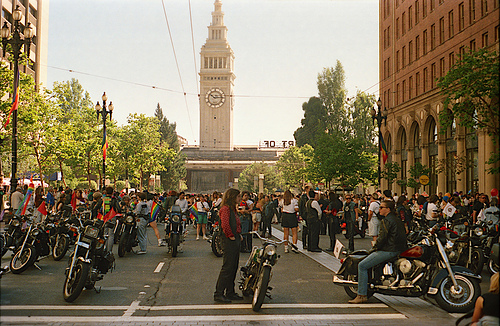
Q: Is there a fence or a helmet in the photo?
A: No, there are no fences or helmets.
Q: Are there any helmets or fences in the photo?
A: No, there are no fences or helmets.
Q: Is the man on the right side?
A: Yes, the man is on the right of the image.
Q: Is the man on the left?
A: No, the man is on the right of the image.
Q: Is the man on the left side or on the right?
A: The man is on the right of the image.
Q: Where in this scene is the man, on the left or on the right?
A: The man is on the right of the image.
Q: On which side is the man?
A: The man is on the right of the image.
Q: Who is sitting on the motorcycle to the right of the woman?
A: The man is sitting on the motorbike.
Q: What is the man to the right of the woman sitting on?
A: The man is sitting on the motorcycle.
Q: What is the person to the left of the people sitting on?
A: The man is sitting on the motorcycle.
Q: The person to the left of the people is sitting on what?
A: The man is sitting on the motorcycle.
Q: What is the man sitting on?
A: The man is sitting on the motorcycle.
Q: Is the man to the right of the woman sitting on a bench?
A: No, the man is sitting on the motorcycle.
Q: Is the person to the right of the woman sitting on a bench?
A: No, the man is sitting on the motorcycle.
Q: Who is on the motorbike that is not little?
A: The man is on the motorbike.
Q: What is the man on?
A: The man is on the motorcycle.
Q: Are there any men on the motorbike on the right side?
A: Yes, there is a man on the motorcycle.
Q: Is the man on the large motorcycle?
A: Yes, the man is on the motorbike.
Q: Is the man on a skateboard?
A: No, the man is on the motorbike.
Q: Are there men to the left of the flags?
A: Yes, there is a man to the left of the flags.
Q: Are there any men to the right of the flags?
A: No, the man is to the left of the flags.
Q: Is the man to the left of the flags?
A: Yes, the man is to the left of the flags.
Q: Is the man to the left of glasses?
A: No, the man is to the left of the flags.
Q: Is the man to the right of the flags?
A: No, the man is to the left of the flags.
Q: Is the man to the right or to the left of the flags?
A: The man is to the left of the flags.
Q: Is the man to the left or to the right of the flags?
A: The man is to the left of the flags.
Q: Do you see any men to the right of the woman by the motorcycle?
A: Yes, there is a man to the right of the woman.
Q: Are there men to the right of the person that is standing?
A: Yes, there is a man to the right of the woman.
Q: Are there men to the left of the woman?
A: No, the man is to the right of the woman.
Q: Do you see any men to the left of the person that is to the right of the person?
A: No, the man is to the right of the woman.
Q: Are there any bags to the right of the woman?
A: No, there is a man to the right of the woman.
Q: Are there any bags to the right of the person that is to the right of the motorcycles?
A: No, there is a man to the right of the woman.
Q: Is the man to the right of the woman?
A: Yes, the man is to the right of the woman.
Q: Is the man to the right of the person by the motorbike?
A: Yes, the man is to the right of the woman.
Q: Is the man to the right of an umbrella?
A: No, the man is to the right of the woman.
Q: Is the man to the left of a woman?
A: No, the man is to the right of a woman.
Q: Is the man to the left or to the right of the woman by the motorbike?
A: The man is to the right of the woman.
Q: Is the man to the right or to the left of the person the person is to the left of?
A: The man is to the right of the woman.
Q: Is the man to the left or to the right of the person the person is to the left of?
A: The man is to the right of the woman.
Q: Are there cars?
A: No, there are no cars.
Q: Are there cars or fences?
A: No, there are no cars or fences.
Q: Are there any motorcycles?
A: Yes, there is a motorcycle.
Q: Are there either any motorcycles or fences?
A: Yes, there is a motorcycle.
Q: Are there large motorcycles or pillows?
A: Yes, there is a large motorcycle.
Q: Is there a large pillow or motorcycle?
A: Yes, there is a large motorcycle.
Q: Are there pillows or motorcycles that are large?
A: Yes, the motorcycle is large.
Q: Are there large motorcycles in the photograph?
A: Yes, there is a large motorcycle.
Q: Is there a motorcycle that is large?
A: Yes, there is a motorcycle that is large.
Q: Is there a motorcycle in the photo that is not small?
A: Yes, there is a large motorcycle.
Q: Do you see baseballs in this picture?
A: No, there are no baseballs.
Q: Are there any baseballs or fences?
A: No, there are no baseballs or fences.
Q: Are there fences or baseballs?
A: No, there are no baseballs or fences.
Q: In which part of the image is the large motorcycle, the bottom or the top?
A: The motorbike is in the bottom of the image.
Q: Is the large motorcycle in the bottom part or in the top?
A: The motorbike is in the bottom of the image.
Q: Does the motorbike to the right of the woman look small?
A: No, the motorcycle is large.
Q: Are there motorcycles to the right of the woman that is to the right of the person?
A: Yes, there is a motorcycle to the right of the woman.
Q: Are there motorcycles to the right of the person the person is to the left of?
A: Yes, there is a motorcycle to the right of the woman.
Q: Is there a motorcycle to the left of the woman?
A: No, the motorcycle is to the right of the woman.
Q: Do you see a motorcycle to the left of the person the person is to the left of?
A: No, the motorcycle is to the right of the woman.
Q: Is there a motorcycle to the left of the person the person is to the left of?
A: No, the motorcycle is to the right of the woman.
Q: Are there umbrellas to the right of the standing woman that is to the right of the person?
A: No, there is a motorcycle to the right of the woman.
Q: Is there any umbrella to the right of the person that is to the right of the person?
A: No, there is a motorcycle to the right of the woman.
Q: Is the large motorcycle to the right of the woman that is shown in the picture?
A: Yes, the motorbike is to the right of the woman.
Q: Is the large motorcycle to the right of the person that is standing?
A: Yes, the motorbike is to the right of the woman.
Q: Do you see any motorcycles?
A: Yes, there are motorcycles.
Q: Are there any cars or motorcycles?
A: Yes, there are motorcycles.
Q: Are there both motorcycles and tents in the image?
A: No, there are motorcycles but no tents.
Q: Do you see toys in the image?
A: No, there are no toys.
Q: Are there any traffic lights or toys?
A: No, there are no toys or traffic lights.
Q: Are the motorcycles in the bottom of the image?
A: Yes, the motorcycles are in the bottom of the image.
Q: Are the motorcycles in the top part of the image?
A: No, the motorcycles are in the bottom of the image.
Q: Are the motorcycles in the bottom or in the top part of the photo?
A: The motorcycles are in the bottom of the image.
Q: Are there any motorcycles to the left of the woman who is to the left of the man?
A: Yes, there are motorcycles to the left of the woman.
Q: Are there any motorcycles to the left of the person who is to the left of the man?
A: Yes, there are motorcycles to the left of the woman.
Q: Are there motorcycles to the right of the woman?
A: No, the motorcycles are to the left of the woman.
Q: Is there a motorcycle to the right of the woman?
A: No, the motorcycles are to the left of the woman.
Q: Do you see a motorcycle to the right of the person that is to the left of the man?
A: No, the motorcycles are to the left of the woman.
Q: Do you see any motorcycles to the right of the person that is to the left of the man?
A: No, the motorcycles are to the left of the woman.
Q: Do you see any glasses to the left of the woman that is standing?
A: No, there are motorcycles to the left of the woman.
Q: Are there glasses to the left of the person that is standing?
A: No, there are motorcycles to the left of the woman.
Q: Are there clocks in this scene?
A: Yes, there is a clock.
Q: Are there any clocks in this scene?
A: Yes, there is a clock.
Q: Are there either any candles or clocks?
A: Yes, there is a clock.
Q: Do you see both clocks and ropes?
A: No, there is a clock but no ropes.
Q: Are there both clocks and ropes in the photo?
A: No, there is a clock but no ropes.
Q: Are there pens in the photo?
A: No, there are no pens.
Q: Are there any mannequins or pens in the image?
A: No, there are no pens or mannequins.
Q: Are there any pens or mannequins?
A: No, there are no pens or mannequins.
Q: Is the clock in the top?
A: Yes, the clock is in the top of the image.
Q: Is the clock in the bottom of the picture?
A: No, the clock is in the top of the image.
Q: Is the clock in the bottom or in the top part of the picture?
A: The clock is in the top of the image.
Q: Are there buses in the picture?
A: No, there are no buses.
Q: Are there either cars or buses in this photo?
A: No, there are no buses or cars.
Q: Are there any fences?
A: No, there are no fences.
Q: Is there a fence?
A: No, there are no fences.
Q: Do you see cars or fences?
A: No, there are no fences or cars.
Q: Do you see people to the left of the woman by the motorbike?
A: Yes, there is a person to the left of the woman.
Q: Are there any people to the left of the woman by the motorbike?
A: Yes, there is a person to the left of the woman.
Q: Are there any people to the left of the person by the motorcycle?
A: Yes, there is a person to the left of the woman.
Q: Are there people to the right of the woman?
A: No, the person is to the left of the woman.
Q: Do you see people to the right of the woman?
A: No, the person is to the left of the woman.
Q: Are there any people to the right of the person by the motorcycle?
A: No, the person is to the left of the woman.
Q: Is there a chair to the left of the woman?
A: No, there is a person to the left of the woman.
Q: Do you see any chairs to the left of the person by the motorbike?
A: No, there is a person to the left of the woman.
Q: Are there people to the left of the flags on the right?
A: Yes, there are people to the left of the flags.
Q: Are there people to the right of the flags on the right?
A: No, the people are to the left of the flags.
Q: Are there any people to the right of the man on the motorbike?
A: Yes, there are people to the right of the man.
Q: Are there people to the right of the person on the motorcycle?
A: Yes, there are people to the right of the man.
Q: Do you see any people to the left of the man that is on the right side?
A: No, the people are to the right of the man.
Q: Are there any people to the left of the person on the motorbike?
A: No, the people are to the right of the man.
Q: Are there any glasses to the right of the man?
A: No, there are people to the right of the man.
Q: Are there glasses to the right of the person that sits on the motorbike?
A: No, there are people to the right of the man.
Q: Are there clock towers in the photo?
A: Yes, there is a clock tower.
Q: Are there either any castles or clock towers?
A: Yes, there is a clock tower.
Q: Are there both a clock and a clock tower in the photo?
A: Yes, there are both a clock tower and a clock.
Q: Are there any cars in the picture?
A: No, there are no cars.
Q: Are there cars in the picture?
A: No, there are no cars.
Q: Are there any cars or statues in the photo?
A: No, there are no cars or statues.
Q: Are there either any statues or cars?
A: No, there are no cars or statues.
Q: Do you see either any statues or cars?
A: No, there are no cars or statues.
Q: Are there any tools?
A: No, there are no tools.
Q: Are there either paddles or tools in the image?
A: No, there are no tools or paddles.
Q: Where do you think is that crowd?
A: The crowd is on the road.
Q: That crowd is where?
A: The crowd is on the road.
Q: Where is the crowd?
A: The crowd is on the road.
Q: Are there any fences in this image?
A: No, there are no fences.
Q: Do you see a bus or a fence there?
A: No, there are no fences or buses.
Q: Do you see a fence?
A: No, there are no fences.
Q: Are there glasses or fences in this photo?
A: No, there are no fences or glasses.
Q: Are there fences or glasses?
A: No, there are no fences or glasses.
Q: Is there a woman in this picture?
A: Yes, there is a woman.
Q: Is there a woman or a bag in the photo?
A: Yes, there is a woman.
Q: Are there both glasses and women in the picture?
A: No, there is a woman but no glasses.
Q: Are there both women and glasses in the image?
A: No, there is a woman but no glasses.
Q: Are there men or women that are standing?
A: Yes, the woman is standing.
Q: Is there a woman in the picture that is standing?
A: Yes, there is a woman that is standing.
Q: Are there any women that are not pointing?
A: Yes, there is a woman that is standing.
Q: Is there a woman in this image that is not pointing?
A: Yes, there is a woman that is standing.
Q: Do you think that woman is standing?
A: Yes, the woman is standing.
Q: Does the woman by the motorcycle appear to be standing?
A: Yes, the woman is standing.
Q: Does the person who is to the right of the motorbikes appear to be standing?
A: Yes, the woman is standing.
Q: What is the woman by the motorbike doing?
A: The woman is standing.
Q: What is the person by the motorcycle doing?
A: The woman is standing.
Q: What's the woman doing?
A: The woman is standing.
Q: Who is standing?
A: The woman is standing.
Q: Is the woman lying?
A: No, the woman is standing.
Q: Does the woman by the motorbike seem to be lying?
A: No, the woman is standing.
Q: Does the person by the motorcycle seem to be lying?
A: No, the woman is standing.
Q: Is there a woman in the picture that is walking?
A: No, there is a woman but she is standing.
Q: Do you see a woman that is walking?
A: No, there is a woman but she is standing.